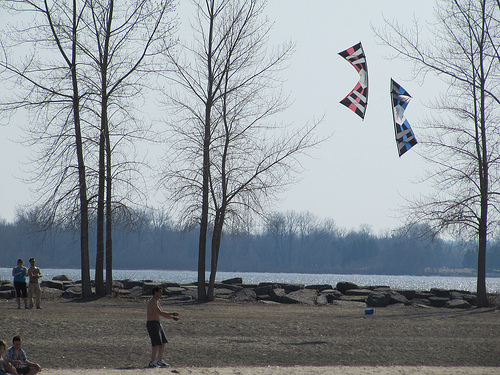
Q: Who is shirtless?
A: The guy in black shorts.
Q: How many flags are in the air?
A: Two.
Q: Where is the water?
A: Behind the rocks.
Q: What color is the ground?
A: Brown.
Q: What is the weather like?
A: Sunny.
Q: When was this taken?
A: During the day.